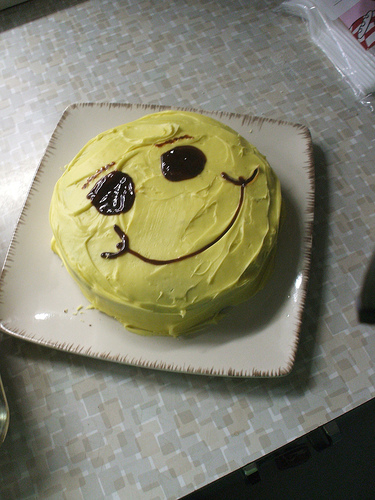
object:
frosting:
[48, 107, 284, 340]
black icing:
[161, 145, 207, 182]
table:
[0, 0, 375, 500]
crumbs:
[64, 308, 68, 313]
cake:
[47, 108, 286, 337]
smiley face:
[81, 132, 260, 269]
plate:
[0, 100, 314, 380]